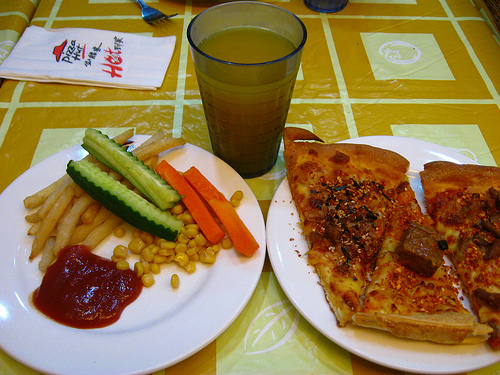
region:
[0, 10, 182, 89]
white napkin with logo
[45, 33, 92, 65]
logo on a napkin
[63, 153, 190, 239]
peice of food on a plate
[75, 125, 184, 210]
peice of food on a plate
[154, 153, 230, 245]
peice of food on a plate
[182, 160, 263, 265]
peice of food on a plate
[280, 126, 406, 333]
peice of food on a plate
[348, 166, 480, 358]
peice of food on a plate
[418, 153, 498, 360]
peice of food on a plate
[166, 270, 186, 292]
peice of food on a plate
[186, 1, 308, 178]
the cup on the table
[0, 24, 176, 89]
the napkins on the table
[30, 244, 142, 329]
the ketchup on the plate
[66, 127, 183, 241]
the cucumbers on the plate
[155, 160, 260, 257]
the carrots on the plate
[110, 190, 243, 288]
the corn on the plate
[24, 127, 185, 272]
the fries on the plate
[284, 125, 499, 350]
the pizza slices on the plate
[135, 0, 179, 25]
the fork on the table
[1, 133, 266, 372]
the white plate under the food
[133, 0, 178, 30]
part of a silver fork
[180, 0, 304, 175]
a large green glass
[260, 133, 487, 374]
a white plate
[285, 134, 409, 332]
a slice of pizza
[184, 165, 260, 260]
a long carrot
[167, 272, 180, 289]
a small piece of corn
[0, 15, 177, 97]
a napkin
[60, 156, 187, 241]
a long green pickle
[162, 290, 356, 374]
part of a yellow tablecloth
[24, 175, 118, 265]
a portion of french fries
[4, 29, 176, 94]
a white paper napkin with a Pizza Hut logo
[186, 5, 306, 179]
plastic drink glass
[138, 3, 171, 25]
metal fork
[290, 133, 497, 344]
three pieces of pizza on a plate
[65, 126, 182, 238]
two zucchini spears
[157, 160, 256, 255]
two carrot sticks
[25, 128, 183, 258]
several french fries under the zucchini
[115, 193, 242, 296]
corn under carrots and zucchini sticks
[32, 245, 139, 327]
red ketchup on a plate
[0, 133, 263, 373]
white plate with vegetables on it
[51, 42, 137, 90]
red and white napkin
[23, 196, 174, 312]
white plate with food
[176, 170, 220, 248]
carrot sticks on plate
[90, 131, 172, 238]
zucchini on white plate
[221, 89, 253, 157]
blue cup with juice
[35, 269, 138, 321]
big blob of ketchup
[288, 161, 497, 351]
plate with pizza slices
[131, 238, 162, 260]
corn on white plate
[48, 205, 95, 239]
french fries on plate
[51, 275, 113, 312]
ketchup is red and wet